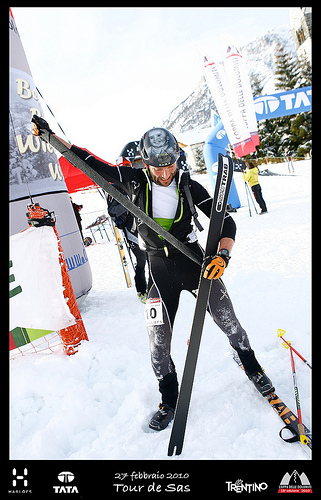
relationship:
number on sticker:
[143, 307, 158, 319] [139, 295, 170, 328]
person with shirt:
[240, 159, 268, 216] [240, 167, 260, 188]